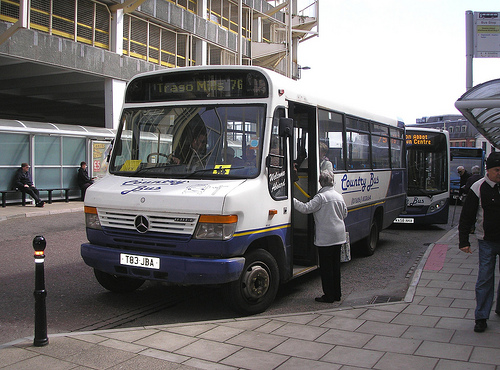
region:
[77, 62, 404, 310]
bus at a stop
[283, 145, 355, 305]
a lady is standing at a bus door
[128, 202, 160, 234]
mercedes symbol on the front of the bus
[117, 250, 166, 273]
license plate on the front of the bus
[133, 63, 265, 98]
marquee screen in the top of the bus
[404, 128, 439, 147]
orange digital text on the top of the bus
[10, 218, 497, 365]
brick paver side walk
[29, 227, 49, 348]
a short black post on the sidewalk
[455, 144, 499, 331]
a man standing on the sidewalk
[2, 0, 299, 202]
a building in the background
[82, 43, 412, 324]
Black blue and white bus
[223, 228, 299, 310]
Black tire on b us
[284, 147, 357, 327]
Woman about to board bus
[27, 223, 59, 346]
Black street pole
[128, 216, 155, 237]
Silver BMW logo on bus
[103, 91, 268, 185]
Large bus window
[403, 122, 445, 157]
Black destination sign on bus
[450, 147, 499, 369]
Man standing on sidewalk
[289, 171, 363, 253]
Woman in white jacket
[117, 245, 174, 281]
Black and white license plate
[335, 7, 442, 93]
Sky is white color.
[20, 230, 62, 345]
Pole is black color.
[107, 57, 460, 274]
Two bus are standing in the road.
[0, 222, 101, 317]
Road is grey color.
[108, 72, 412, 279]
Bus is white and blue color.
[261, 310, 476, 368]
Sidewalk is grey color.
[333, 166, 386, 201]
Letters are blue color.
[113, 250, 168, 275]
Number plate is white and black color.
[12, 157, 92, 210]
Two men are sitting in the bench.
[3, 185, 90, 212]
Bench is black color.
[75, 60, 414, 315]
A big blue and white bus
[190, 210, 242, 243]
The left headlight of the bus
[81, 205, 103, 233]
The right headlight of the bus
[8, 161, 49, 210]
A person sitting on the chair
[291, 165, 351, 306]
A woman standing infront of the bus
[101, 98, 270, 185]
The front window of the bus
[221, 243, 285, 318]
The left tire of the bus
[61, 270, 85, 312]
Part of the road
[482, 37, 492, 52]
Part of the sign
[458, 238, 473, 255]
The right hand of the person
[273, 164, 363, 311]
Man about to enter bus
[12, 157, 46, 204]
Man sitting on a bench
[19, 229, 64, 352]
Black pole on the sidewalk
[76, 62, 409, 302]
Bus on the road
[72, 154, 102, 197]
Woman sitting on a bench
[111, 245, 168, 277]
White plate on bus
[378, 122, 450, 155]
Digital sign on bus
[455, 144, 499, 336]
Man wearing blue jeans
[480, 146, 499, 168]
Cap on man's head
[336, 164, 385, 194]
Blue writing on side of bus